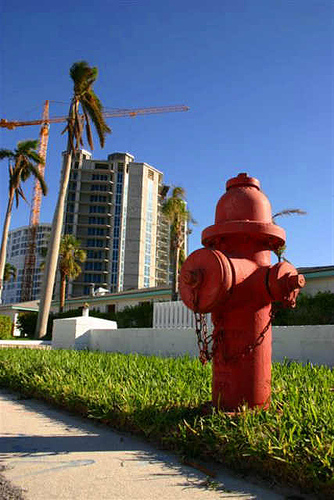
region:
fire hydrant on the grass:
[178, 169, 302, 408]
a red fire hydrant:
[177, 173, 304, 414]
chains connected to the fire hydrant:
[187, 274, 299, 364]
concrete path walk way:
[0, 384, 288, 497]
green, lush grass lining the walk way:
[0, 345, 332, 496]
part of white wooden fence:
[152, 301, 211, 328]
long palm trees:
[1, 60, 111, 339]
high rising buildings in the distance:
[1, 146, 185, 302]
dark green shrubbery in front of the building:
[13, 291, 331, 335]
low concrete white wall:
[54, 320, 332, 362]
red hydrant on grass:
[175, 168, 272, 433]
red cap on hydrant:
[187, 122, 292, 245]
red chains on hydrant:
[196, 299, 296, 386]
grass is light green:
[279, 386, 333, 477]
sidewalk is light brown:
[11, 433, 114, 496]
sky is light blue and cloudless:
[212, 38, 315, 166]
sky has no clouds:
[193, 68, 305, 161]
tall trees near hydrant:
[0, 63, 136, 282]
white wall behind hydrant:
[85, 284, 282, 366]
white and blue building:
[68, 151, 173, 309]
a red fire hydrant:
[172, 170, 304, 405]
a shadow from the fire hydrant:
[3, 405, 230, 448]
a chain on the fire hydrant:
[186, 294, 291, 378]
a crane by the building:
[5, 88, 208, 328]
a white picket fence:
[147, 296, 231, 333]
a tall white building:
[62, 143, 193, 321]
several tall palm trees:
[0, 72, 213, 362]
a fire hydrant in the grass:
[186, 166, 313, 434]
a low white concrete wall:
[50, 304, 332, 371]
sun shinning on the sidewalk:
[5, 390, 269, 498]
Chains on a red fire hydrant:
[191, 291, 289, 364]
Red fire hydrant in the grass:
[175, 168, 305, 415]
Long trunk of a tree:
[34, 123, 74, 342]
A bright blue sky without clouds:
[0, 1, 332, 265]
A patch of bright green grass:
[1, 342, 333, 493]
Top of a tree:
[60, 54, 113, 156]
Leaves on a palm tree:
[0, 139, 48, 194]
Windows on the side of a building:
[11, 226, 48, 257]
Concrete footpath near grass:
[1, 385, 292, 499]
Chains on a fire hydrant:
[187, 285, 293, 364]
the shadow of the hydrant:
[0, 420, 156, 468]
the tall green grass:
[8, 351, 186, 454]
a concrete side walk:
[0, 396, 318, 497]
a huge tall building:
[2, 135, 200, 337]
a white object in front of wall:
[141, 287, 222, 340]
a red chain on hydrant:
[162, 288, 285, 366]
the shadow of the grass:
[130, 430, 244, 498]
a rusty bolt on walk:
[166, 449, 228, 484]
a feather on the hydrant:
[268, 202, 312, 233]